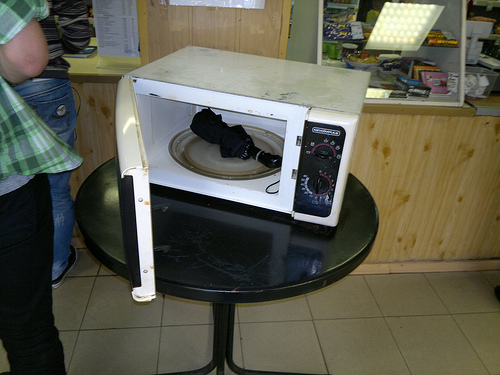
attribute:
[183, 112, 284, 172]
umbrella — black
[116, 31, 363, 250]
microwave — sitting, dirty, old, white, open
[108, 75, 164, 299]
door — open, white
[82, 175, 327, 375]
table — black, round, wooden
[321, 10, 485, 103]
display — glass, full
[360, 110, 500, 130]
counter — wood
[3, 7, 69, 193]
shirt — plaid, green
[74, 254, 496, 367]
floor — tile, tiled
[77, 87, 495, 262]
wall — tan, wood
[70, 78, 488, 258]
wood — tan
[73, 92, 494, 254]
paneling — wood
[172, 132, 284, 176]
microwave tray — glass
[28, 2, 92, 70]
shirt — grey, striped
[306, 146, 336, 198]
buttons — black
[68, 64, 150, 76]
board — wooden